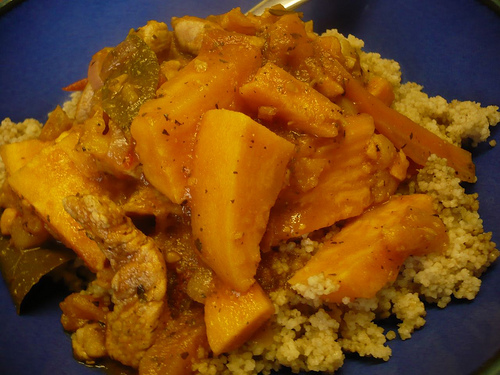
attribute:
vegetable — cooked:
[187, 97, 304, 312]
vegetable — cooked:
[183, 259, 284, 349]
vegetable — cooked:
[8, 145, 167, 313]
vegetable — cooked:
[127, 29, 267, 202]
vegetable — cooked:
[189, 42, 348, 145]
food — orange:
[291, 189, 450, 306]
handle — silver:
[242, 0, 313, 14]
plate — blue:
[2, 3, 482, 373]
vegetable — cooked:
[120, 38, 269, 211]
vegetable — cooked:
[8, 129, 140, 276]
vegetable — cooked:
[197, 288, 278, 358]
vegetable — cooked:
[273, 189, 442, 309]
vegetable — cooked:
[263, 111, 394, 251]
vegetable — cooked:
[238, 63, 345, 146]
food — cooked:
[187, 13, 484, 372]